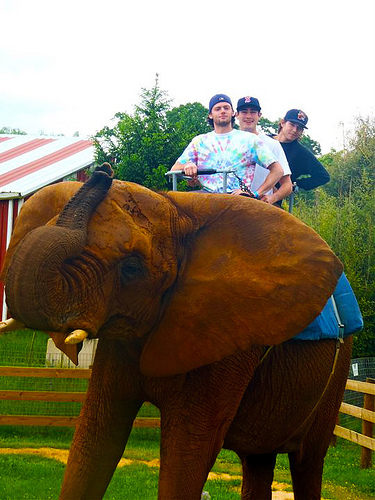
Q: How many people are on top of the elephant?
A: 3.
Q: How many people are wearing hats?
A: 3.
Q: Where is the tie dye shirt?
A: On the man.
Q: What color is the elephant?
A: Brown.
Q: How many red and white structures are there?
A: 1.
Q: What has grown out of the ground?
A: Grass and trees.